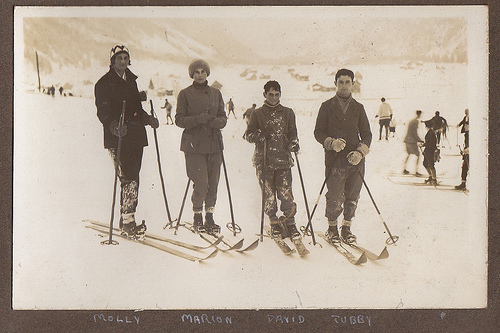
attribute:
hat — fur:
[188, 58, 210, 76]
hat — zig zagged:
[111, 44, 126, 54]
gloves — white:
[331, 136, 359, 163]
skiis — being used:
[85, 219, 223, 263]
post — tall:
[34, 50, 42, 88]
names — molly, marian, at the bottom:
[92, 314, 246, 330]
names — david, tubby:
[264, 308, 373, 328]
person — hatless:
[247, 100, 301, 224]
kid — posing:
[314, 69, 372, 241]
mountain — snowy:
[26, 17, 466, 75]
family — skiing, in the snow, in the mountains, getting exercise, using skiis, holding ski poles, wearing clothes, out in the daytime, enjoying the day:
[92, 43, 368, 250]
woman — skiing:
[405, 108, 423, 177]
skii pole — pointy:
[148, 98, 172, 224]